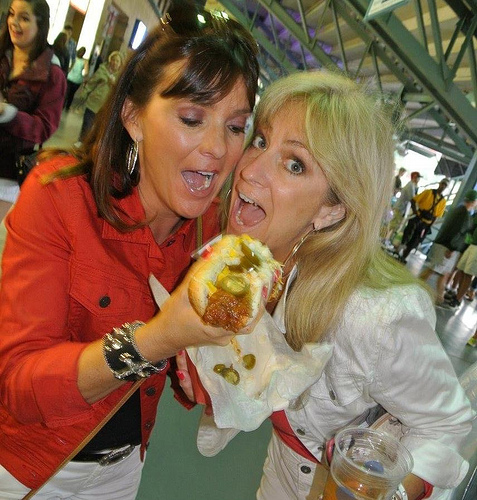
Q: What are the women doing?
A: Eating a hotdog.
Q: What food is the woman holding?
A: A hotdog in a bun.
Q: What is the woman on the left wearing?
A: A red shirt and white pants.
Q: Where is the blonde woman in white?
A: Next to the woman in a red shirt.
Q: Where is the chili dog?
A: In the woman's hand.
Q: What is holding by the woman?
A: A beverage.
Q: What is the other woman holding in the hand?
A: A sandwich.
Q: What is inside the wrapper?
A: Jalapenos.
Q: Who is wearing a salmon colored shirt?
A: The woman.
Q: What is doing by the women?
A: Sharing food.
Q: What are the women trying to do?
A: Eating Food.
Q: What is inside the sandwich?
A: Chili cheese hot dog.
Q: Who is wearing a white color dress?
A: The woman.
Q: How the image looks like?
A: Fun.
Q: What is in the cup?
A: Beer.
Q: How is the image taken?
A: Front of camera.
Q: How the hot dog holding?
A: Hand.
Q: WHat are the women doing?
A: Eating.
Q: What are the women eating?
A: Hot dog.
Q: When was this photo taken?
A: Daytime.